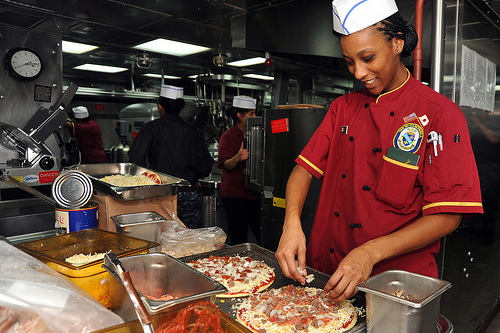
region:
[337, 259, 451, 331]
a silver container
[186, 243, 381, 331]
two pizzas on a silver tray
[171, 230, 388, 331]
a silver tray with two pizzas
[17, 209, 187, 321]
a yellow container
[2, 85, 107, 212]
a silver deli slicer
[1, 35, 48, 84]
a white and black clock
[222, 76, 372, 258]
a silver oven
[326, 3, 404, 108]
a woman smiling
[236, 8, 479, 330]
a woman making a pizza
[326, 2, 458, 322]
a woman wearing a red shirt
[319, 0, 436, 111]
The woman is smiling.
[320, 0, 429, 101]
The woman is wearing a hat.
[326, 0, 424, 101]
The woman's hate is paper.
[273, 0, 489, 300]
The woman is wearing a red shirt.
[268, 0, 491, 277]
The woman's shirt is trimmed in yellow.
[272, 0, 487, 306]
The woman's shirt has a chest pocket.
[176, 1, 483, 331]
The woman is preparing pizza.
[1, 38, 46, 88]
The clock is round.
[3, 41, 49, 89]
The clock case is black.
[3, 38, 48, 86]
The clock face is white.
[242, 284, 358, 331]
An uncooked pizza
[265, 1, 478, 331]
A lady making a pizza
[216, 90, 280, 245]
A person with her hand on the oven door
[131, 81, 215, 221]
The person is wearing a white hat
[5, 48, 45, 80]
A wall clock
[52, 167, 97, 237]
An open can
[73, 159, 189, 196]
A metal baking pan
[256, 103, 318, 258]
An industrial pizza oven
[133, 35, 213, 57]
Ceiling light fixture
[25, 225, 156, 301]
A container of mozzarella cheese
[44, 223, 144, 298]
Gold bin of shredded pizza cheese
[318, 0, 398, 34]
White chef's hat with blue stripe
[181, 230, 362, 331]
Two made from scratch pizzas on cookie sheet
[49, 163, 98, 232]
Metal can with lid opened and still attached and raised up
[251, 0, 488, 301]
Smiling woman preparing pizzas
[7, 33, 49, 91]
Wall clock hanging on wall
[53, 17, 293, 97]
Flourescent lights in ceiling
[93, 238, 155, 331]
Pair of metal tongs overlapping metal bin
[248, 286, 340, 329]
Sausage and pepperoni on pizza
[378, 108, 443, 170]
Fancy patches on chef coat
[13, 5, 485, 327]
cookers in a kitchen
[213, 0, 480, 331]
woman making pizza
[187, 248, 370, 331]
two uncooked pizza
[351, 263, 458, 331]
a silver bowl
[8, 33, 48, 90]
a clock on a wall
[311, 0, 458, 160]
woman wears a white cap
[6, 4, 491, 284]
people in kitchen wears red uniform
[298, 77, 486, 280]
red uniform with yellow stripes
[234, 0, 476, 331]
woman putting cheese on pizza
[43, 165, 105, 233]
an open blue can